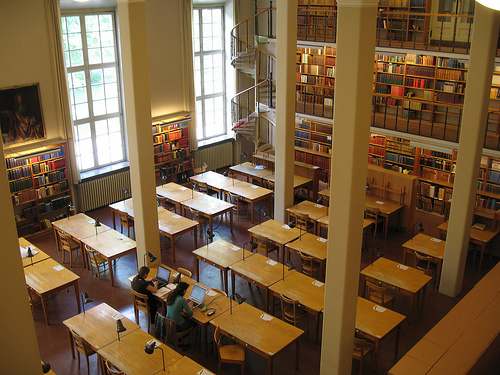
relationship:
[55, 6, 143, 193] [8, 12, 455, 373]
windows in library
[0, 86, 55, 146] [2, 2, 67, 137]
painting in wall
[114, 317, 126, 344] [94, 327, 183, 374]
lamp on desk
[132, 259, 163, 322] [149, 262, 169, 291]
person on laptop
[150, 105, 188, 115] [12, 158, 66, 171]
track lighting on books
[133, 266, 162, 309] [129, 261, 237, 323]
person on table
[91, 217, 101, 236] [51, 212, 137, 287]
black lamp on desk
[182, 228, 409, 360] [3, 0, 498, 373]
table wearing library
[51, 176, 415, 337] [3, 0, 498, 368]
tables in hall